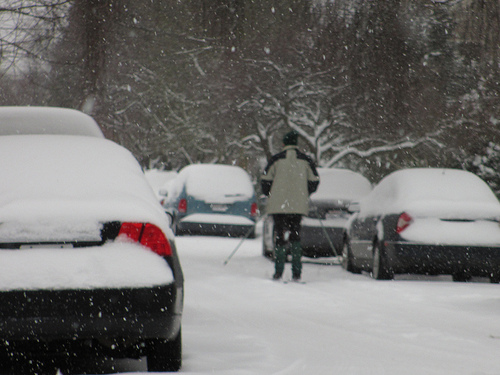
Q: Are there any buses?
A: No, there are no buses.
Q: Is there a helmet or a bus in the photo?
A: No, there are no buses or helmets.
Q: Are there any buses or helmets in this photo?
A: No, there are no buses or helmets.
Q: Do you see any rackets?
A: No, there are no rackets.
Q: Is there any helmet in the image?
A: No, there are no helmets.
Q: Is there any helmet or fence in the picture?
A: No, there are no helmets or fences.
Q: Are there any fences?
A: No, there are no fences.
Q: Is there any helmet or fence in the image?
A: No, there are no fences or helmets.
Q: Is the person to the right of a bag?
A: No, the person is to the right of the car.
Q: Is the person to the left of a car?
A: No, the person is to the right of a car.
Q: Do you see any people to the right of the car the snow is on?
A: Yes, there is a person to the right of the car.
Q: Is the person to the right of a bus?
A: No, the person is to the right of a car.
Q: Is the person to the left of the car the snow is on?
A: No, the person is to the right of the car.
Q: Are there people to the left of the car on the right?
A: Yes, there is a person to the left of the car.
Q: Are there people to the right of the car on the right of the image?
A: No, the person is to the left of the car.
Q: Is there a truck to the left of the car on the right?
A: No, there is a person to the left of the car.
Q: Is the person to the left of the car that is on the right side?
A: Yes, the person is to the left of the car.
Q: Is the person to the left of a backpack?
A: No, the person is to the left of the car.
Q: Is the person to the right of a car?
A: No, the person is to the left of a car.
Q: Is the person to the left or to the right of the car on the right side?
A: The person is to the left of the car.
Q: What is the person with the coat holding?
A: The person is holding the pole.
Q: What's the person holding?
A: The person is holding the pole.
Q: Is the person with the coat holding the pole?
A: Yes, the person is holding the pole.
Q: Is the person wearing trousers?
A: Yes, the person is wearing trousers.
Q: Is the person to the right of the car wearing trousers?
A: Yes, the person is wearing trousers.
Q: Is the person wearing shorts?
A: No, the person is wearing trousers.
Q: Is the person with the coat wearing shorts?
A: No, the person is wearing trousers.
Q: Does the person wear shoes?
A: Yes, the person wears shoes.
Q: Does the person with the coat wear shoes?
A: Yes, the person wears shoes.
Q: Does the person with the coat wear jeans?
A: No, the person wears shoes.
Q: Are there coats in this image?
A: Yes, there is a coat.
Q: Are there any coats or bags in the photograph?
A: Yes, there is a coat.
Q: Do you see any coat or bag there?
A: Yes, there is a coat.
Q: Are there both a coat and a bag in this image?
A: No, there is a coat but no bags.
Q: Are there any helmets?
A: No, there are no helmets.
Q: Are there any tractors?
A: No, there are no tractors.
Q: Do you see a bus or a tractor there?
A: No, there are no tractors or buses.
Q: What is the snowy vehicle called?
A: The vehicle is a car.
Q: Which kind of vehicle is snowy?
A: The vehicle is a car.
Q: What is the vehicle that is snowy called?
A: The vehicle is a car.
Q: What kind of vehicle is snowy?
A: The vehicle is a car.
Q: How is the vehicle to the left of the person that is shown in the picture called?
A: The vehicle is a car.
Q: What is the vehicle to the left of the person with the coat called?
A: The vehicle is a car.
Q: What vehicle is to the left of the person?
A: The vehicle is a car.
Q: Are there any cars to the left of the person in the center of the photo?
A: Yes, there is a car to the left of the person.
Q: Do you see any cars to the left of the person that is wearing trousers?
A: Yes, there is a car to the left of the person.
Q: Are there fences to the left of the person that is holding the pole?
A: No, there is a car to the left of the person.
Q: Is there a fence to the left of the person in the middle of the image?
A: No, there is a car to the left of the person.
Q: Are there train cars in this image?
A: No, there are no train cars.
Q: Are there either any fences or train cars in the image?
A: No, there are no train cars or fences.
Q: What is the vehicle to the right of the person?
A: The vehicle is a car.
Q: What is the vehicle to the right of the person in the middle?
A: The vehicle is a car.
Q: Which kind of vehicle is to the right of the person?
A: The vehicle is a car.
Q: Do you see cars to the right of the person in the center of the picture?
A: Yes, there is a car to the right of the person.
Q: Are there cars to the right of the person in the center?
A: Yes, there is a car to the right of the person.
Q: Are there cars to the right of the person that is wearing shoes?
A: Yes, there is a car to the right of the person.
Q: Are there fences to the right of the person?
A: No, there is a car to the right of the person.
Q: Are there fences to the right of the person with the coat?
A: No, there is a car to the right of the person.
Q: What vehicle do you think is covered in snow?
A: The vehicle is a car.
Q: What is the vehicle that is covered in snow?
A: The vehicle is a car.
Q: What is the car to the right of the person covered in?
A: The car is covered in snow.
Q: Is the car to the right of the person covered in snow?
A: Yes, the car is covered in snow.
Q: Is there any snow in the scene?
A: Yes, there is snow.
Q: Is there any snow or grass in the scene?
A: Yes, there is snow.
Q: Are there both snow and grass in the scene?
A: No, there is snow but no grass.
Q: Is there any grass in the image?
A: No, there is no grass.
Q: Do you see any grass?
A: No, there is no grass.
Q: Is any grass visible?
A: No, there is no grass.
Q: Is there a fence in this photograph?
A: No, there are no fences.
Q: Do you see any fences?
A: No, there are no fences.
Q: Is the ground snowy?
A: Yes, the ground is snowy.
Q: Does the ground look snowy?
A: Yes, the ground is snowy.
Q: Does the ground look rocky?
A: No, the ground is snowy.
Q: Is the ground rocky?
A: No, the ground is snowy.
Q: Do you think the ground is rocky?
A: No, the ground is snowy.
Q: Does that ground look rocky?
A: No, the ground is snowy.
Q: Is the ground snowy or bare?
A: The ground is snowy.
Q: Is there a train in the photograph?
A: No, there are no trains.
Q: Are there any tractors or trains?
A: No, there are no trains or tractors.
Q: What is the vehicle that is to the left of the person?
A: The vehicle is a car.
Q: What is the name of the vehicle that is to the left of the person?
A: The vehicle is a car.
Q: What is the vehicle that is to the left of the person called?
A: The vehicle is a car.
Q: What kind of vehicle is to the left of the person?
A: The vehicle is a car.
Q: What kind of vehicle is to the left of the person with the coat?
A: The vehicle is a car.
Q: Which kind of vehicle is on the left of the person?
A: The vehicle is a car.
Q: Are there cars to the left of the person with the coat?
A: Yes, there is a car to the left of the person.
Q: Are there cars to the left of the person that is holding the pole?
A: Yes, there is a car to the left of the person.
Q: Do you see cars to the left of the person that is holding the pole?
A: Yes, there is a car to the left of the person.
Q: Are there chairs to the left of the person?
A: No, there is a car to the left of the person.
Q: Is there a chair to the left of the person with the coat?
A: No, there is a car to the left of the person.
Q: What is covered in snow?
A: The car is covered in snow.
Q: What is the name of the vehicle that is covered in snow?
A: The vehicle is a car.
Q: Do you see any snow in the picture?
A: Yes, there is snow.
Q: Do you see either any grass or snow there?
A: Yes, there is snow.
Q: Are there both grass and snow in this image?
A: No, there is snow but no grass.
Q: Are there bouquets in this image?
A: No, there are no bouquets.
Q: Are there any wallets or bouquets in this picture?
A: No, there are no bouquets or wallets.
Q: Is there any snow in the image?
A: Yes, there is snow.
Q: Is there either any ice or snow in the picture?
A: Yes, there is snow.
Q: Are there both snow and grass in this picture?
A: No, there is snow but no grass.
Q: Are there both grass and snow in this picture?
A: No, there is snow but no grass.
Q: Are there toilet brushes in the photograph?
A: No, there are no toilet brushes.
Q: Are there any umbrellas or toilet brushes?
A: No, there are no toilet brushes or umbrellas.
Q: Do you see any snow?
A: Yes, there is snow.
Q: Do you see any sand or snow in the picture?
A: Yes, there is snow.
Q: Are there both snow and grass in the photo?
A: No, there is snow but no grass.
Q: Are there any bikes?
A: No, there are no bikes.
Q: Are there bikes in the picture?
A: No, there are no bikes.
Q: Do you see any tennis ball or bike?
A: No, there are no bikes or tennis balls.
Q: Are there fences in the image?
A: No, there are no fences.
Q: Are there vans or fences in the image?
A: No, there are no fences or vans.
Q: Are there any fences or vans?
A: No, there are no fences or vans.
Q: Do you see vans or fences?
A: No, there are no fences or vans.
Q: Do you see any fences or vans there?
A: No, there are no fences or vans.